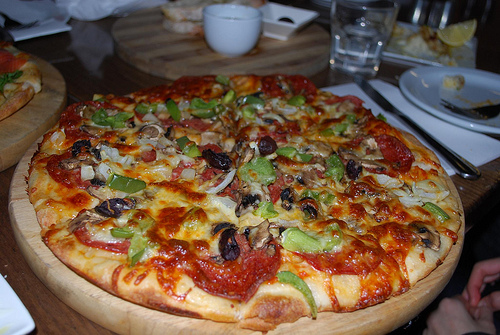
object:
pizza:
[23, 71, 462, 334]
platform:
[6, 133, 467, 335]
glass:
[326, 3, 400, 81]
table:
[0, 1, 500, 335]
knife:
[351, 75, 483, 183]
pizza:
[2, 40, 46, 120]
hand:
[422, 296, 495, 333]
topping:
[219, 229, 241, 260]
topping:
[110, 222, 132, 242]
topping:
[375, 135, 418, 170]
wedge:
[435, 16, 480, 48]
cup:
[62, 0, 129, 21]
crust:
[29, 73, 464, 328]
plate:
[397, 63, 500, 135]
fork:
[440, 98, 500, 123]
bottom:
[0, 293, 500, 335]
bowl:
[201, 0, 266, 58]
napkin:
[321, 79, 500, 176]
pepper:
[190, 96, 217, 118]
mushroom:
[246, 221, 278, 251]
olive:
[299, 196, 315, 206]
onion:
[207, 167, 240, 194]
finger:
[468, 259, 496, 310]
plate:
[108, 7, 337, 79]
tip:
[440, 99, 455, 112]